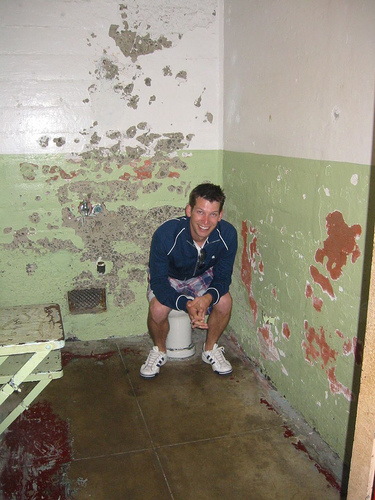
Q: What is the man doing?
A: Using the toilet.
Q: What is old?
A: The wall.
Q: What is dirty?
A: The floor.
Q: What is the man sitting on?
A: A toilet.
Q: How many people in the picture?
A: 1.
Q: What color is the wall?
A: Green.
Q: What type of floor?
A: Concrete.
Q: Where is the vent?
A: On the wall.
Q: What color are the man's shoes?
A: White.